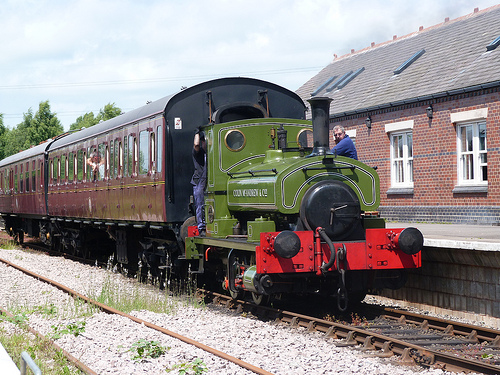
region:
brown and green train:
[14, 86, 412, 308]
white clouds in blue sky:
[41, 18, 106, 85]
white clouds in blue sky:
[247, 26, 312, 71]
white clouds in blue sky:
[150, 35, 171, 65]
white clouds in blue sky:
[11, 19, 49, 59]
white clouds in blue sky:
[98, 33, 138, 70]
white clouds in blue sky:
[42, 39, 86, 80]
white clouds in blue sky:
[70, 18, 134, 85]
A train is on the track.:
[0, 77, 427, 322]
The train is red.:
[367, 230, 395, 266]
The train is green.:
[245, 125, 270, 159]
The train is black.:
[217, 80, 258, 103]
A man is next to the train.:
[330, 123, 359, 155]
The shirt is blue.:
[335, 141, 355, 154]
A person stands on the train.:
[188, 127, 209, 239]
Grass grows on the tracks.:
[96, 285, 173, 314]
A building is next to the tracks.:
[388, 4, 498, 217]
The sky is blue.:
[0, 48, 75, 73]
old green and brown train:
[30, 85, 372, 302]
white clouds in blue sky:
[33, 20, 77, 52]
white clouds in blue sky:
[94, 20, 139, 57]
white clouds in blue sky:
[43, 30, 75, 70]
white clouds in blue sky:
[258, 11, 291, 49]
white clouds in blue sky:
[169, 24, 211, 57]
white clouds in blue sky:
[65, 17, 101, 38]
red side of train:
[19, 140, 172, 233]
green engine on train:
[198, 124, 375, 258]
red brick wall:
[332, 113, 498, 211]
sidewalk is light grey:
[380, 205, 489, 247]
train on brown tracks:
[37, 115, 492, 374]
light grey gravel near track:
[192, 308, 330, 373]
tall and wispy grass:
[27, 266, 173, 346]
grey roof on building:
[298, 26, 498, 108]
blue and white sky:
[120, 10, 215, 67]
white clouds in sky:
[120, 1, 237, 66]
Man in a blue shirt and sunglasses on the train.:
[330, 125, 358, 158]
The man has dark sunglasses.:
[334, 130, 342, 135]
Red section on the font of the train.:
[254, 228, 421, 273]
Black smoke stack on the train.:
[308, 95, 334, 155]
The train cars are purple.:
[6, 75, 306, 285]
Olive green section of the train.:
[206, 118, 380, 241]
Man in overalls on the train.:
[191, 126, 208, 235]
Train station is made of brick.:
[295, 1, 499, 226]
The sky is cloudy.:
[3, 0, 330, 108]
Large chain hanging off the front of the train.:
[335, 245, 350, 312]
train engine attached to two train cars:
[0, 76, 423, 311]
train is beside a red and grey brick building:
[0, 2, 497, 307]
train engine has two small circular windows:
[176, 95, 421, 305]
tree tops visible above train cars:
[0, 75, 425, 310]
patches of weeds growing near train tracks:
[0, 231, 497, 373]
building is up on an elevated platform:
[293, 4, 498, 331]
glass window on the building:
[391, 135, 403, 155]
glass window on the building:
[391, 157, 401, 180]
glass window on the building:
[460, 150, 471, 177]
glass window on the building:
[475, 120, 485, 155]